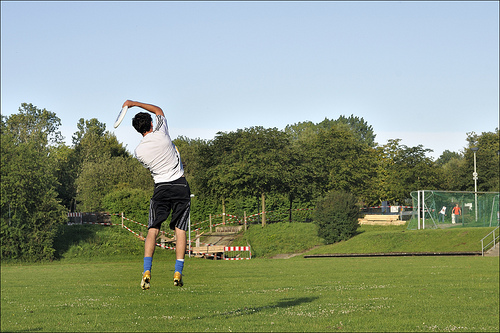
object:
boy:
[122, 99, 195, 292]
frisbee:
[114, 106, 129, 128]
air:
[94, 87, 204, 151]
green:
[221, 132, 265, 170]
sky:
[0, 0, 499, 163]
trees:
[61, 118, 134, 199]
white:
[223, 246, 251, 251]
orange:
[173, 272, 180, 280]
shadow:
[190, 297, 321, 322]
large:
[357, 198, 413, 226]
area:
[334, 154, 500, 242]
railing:
[209, 211, 247, 233]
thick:
[218, 141, 282, 185]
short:
[147, 177, 191, 231]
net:
[408, 191, 481, 230]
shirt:
[133, 114, 184, 183]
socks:
[143, 257, 184, 275]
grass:
[260, 265, 359, 288]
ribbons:
[211, 213, 243, 228]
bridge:
[155, 226, 243, 253]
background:
[199, 225, 249, 246]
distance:
[363, 189, 446, 224]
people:
[451, 203, 461, 224]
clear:
[172, 28, 249, 61]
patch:
[239, 281, 360, 295]